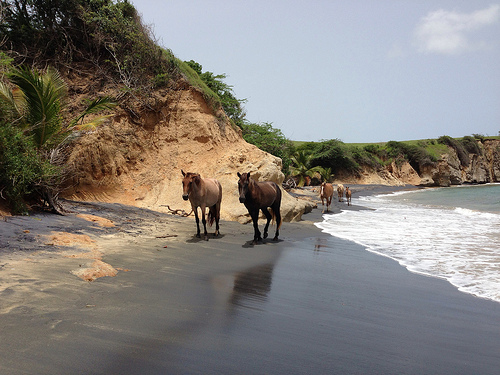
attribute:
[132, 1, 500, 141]
sky — blue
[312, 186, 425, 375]
shore — wet, sandy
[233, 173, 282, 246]
horse — walking, dark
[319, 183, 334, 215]
horse — walking, borwn, standing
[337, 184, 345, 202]
horse — walking, herded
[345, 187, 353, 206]
horse — walking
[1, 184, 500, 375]
beach — black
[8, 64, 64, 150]
plant — large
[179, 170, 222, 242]
horse — walking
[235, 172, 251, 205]
face — dark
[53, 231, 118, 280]
sand — piled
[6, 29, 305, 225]
cliff — dirt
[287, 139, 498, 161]
hill — grassy